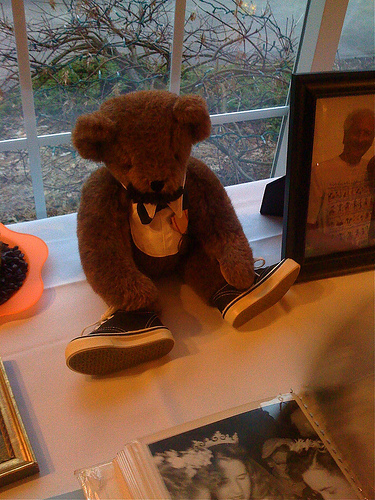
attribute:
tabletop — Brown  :
[287, 294, 372, 389]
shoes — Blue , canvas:
[212, 254, 304, 329]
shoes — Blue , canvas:
[65, 304, 173, 373]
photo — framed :
[281, 70, 373, 284]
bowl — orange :
[0, 219, 50, 320]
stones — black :
[0, 237, 28, 305]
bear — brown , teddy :
[41, 71, 315, 383]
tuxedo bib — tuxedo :
[127, 184, 185, 255]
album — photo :
[75, 374, 372, 498]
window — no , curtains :
[0, 3, 375, 221]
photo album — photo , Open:
[75, 361, 374, 498]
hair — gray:
[344, 108, 374, 128]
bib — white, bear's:
[117, 175, 190, 255]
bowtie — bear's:
[120, 180, 193, 221]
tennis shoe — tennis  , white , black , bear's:
[66, 258, 301, 376]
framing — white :
[7, 48, 72, 157]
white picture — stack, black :
[295, 86, 371, 265]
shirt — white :
[129, 196, 186, 252]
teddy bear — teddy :
[54, 86, 304, 377]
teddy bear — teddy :
[76, 88, 250, 311]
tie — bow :
[138, 192, 190, 222]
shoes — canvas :
[48, 260, 315, 364]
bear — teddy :
[48, 62, 293, 369]